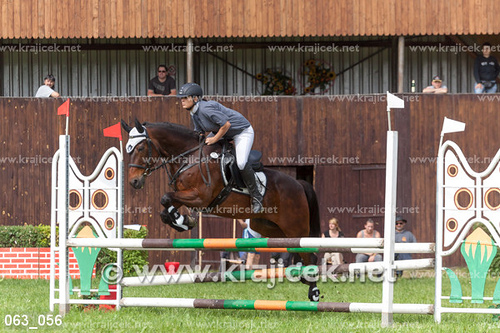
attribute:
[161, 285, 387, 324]
grass — green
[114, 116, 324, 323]
horse — brown, white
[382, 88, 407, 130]
white flag — small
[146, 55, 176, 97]
man — white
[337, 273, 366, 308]
grass — green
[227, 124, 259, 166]
pants — white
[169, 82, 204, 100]
helmet — black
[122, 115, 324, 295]
horse — black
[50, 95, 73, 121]
flag — small, red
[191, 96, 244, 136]
shirt — grey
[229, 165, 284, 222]
boots — black 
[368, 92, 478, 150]
flags — white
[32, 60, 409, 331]
competition — horse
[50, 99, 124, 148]
markers — red, flag